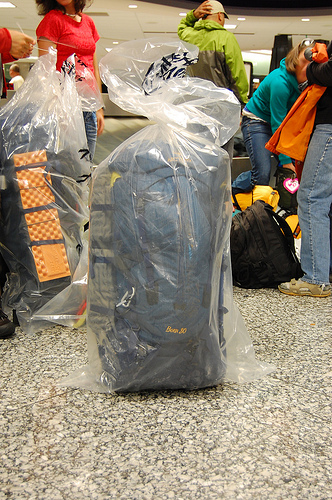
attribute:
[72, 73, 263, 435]
bag — plastic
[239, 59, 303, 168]
sweatshirt — turquoise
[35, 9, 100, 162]
shirt and — red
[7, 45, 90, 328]
bag — plastic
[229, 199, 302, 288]
backpack — black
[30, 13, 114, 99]
shirt — white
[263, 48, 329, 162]
jacket — orange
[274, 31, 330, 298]
person — orange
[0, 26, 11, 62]
sleeves — red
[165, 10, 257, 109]
jacket — green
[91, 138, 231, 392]
pack — hiking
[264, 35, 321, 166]
jacket — orange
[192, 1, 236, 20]
cap — baseball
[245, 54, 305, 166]
hoodie — teal